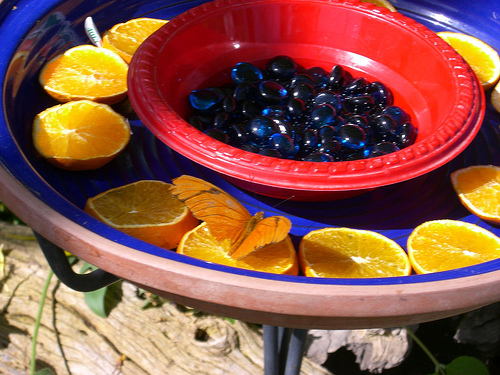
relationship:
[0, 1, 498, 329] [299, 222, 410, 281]
bowl has orange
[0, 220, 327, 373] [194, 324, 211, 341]
wood has a hole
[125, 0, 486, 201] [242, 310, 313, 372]
bowl propped on metal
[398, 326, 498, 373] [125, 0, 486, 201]
leaves below bowl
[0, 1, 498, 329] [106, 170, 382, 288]
bowl of fruit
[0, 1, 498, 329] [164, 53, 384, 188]
bowl of pebbles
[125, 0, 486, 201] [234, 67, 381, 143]
bowl of pebbles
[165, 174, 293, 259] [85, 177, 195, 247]
butterfly on a fruit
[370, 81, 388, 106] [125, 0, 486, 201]
jewel in a bowl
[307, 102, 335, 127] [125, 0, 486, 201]
jewel in a bowl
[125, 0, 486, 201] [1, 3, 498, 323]
bowl on a platter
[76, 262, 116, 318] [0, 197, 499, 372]
leaf on ground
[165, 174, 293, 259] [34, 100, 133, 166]
butterfly on fruit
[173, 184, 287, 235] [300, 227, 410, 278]
butterfly on a fruit